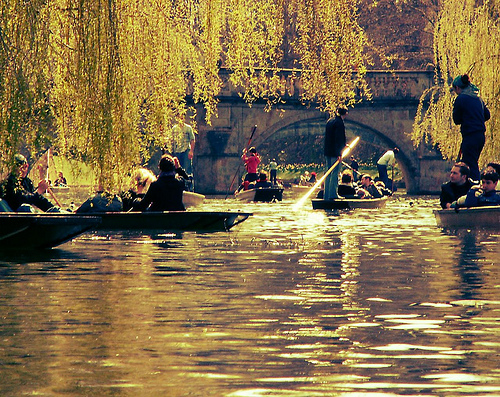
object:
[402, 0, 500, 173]
tree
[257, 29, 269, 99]
branches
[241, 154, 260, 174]
shirt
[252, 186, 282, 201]
stern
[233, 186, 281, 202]
row boat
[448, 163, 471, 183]
head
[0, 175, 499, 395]
river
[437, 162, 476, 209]
people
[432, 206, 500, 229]
boat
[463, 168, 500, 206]
person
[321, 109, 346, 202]
man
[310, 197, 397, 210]
boat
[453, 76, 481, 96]
bandana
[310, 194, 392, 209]
row boat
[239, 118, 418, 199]
archway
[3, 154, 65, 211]
people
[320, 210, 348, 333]
reflection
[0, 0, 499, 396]
background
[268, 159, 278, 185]
person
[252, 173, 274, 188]
person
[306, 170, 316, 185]
person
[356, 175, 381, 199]
person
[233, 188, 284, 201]
boat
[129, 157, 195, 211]
person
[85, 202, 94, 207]
leaf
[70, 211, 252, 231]
boat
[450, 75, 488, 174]
person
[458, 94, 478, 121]
black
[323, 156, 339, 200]
jeans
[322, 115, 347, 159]
shirt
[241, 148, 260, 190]
person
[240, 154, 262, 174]
coat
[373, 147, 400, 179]
person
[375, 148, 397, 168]
shirt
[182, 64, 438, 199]
bridge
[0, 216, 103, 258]
boat